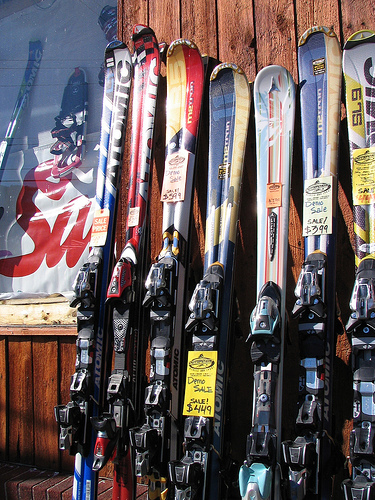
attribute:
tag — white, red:
[89, 208, 111, 248]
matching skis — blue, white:
[187, 61, 230, 472]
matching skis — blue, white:
[296, 22, 334, 473]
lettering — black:
[187, 372, 215, 397]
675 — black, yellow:
[348, 84, 365, 131]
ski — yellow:
[160, 40, 185, 139]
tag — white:
[302, 175, 333, 237]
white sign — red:
[9, 93, 74, 285]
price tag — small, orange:
[261, 179, 283, 212]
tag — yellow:
[178, 347, 223, 425]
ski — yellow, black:
[89, 31, 129, 229]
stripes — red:
[130, 22, 161, 498]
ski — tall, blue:
[50, 39, 135, 498]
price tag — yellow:
[89, 205, 116, 252]